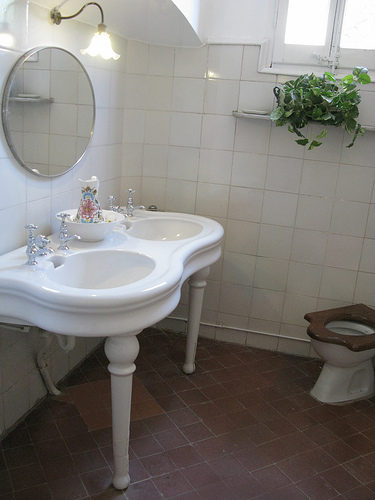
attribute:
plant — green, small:
[272, 65, 370, 151]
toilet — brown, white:
[300, 295, 374, 412]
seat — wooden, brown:
[299, 299, 374, 353]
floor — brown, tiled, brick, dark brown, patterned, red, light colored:
[4, 328, 370, 499]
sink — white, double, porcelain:
[5, 201, 228, 494]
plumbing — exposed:
[8, 321, 80, 406]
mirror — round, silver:
[3, 45, 97, 180]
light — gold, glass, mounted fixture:
[49, 2, 124, 68]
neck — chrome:
[60, 3, 107, 32]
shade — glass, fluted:
[79, 31, 120, 63]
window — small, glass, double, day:
[263, 1, 374, 82]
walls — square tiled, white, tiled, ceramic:
[5, 4, 374, 358]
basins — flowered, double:
[53, 209, 193, 294]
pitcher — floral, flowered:
[76, 176, 107, 225]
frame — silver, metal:
[8, 43, 98, 180]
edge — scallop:
[81, 47, 117, 60]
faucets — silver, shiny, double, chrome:
[16, 186, 145, 268]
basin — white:
[57, 209, 123, 243]